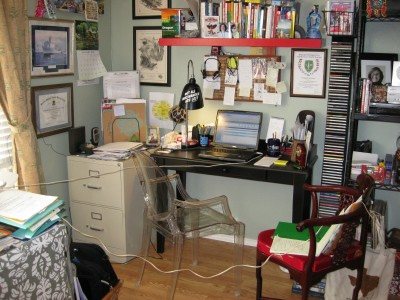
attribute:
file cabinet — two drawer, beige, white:
[63, 143, 156, 261]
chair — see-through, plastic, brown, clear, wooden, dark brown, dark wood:
[131, 153, 245, 298]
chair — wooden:
[254, 173, 367, 298]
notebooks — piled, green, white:
[273, 222, 331, 257]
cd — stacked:
[330, 90, 348, 105]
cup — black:
[267, 137, 281, 157]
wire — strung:
[14, 153, 266, 182]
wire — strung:
[50, 203, 388, 278]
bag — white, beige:
[324, 199, 397, 300]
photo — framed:
[150, 129, 156, 141]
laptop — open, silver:
[209, 108, 258, 162]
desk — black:
[153, 131, 310, 263]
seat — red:
[258, 224, 362, 268]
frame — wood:
[145, 122, 162, 152]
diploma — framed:
[30, 87, 75, 130]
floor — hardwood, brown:
[96, 233, 328, 300]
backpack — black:
[67, 240, 120, 298]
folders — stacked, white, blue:
[9, 195, 68, 242]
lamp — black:
[180, 59, 204, 149]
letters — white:
[181, 90, 198, 103]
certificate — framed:
[296, 56, 322, 92]